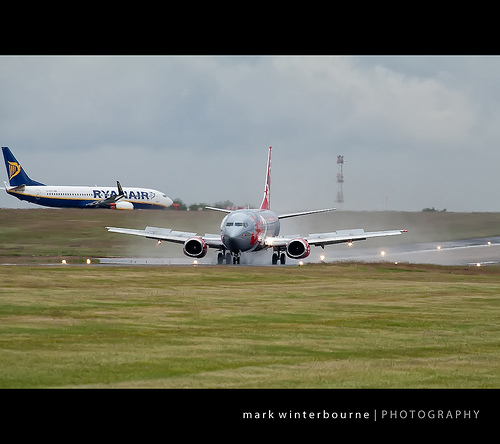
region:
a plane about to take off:
[112, 152, 424, 287]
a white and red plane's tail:
[258, 143, 286, 211]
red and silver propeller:
[283, 231, 315, 265]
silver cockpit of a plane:
[218, 212, 258, 257]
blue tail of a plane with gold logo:
[1, 143, 38, 189]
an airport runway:
[414, 231, 499, 268]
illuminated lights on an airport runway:
[316, 239, 495, 256]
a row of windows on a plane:
[47, 187, 94, 197]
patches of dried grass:
[133, 270, 385, 315]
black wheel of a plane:
[214, 246, 292, 275]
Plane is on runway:
[105, 214, 412, 271]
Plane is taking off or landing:
[1, 145, 186, 220]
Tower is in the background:
[323, 147, 354, 214]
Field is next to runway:
[8, 261, 496, 381]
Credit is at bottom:
[5, 392, 499, 428]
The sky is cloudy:
[1, 55, 497, 152]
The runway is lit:
[51, 214, 493, 268]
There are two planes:
[0, 142, 421, 267]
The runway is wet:
[78, 225, 478, 266]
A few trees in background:
[171, 197, 243, 214]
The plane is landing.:
[56, 148, 446, 305]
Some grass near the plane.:
[45, 280, 476, 370]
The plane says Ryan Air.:
[5, 142, 226, 232]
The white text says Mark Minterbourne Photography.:
[230, 397, 490, 425]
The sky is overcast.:
[33, 65, 488, 145]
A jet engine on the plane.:
[281, 235, 316, 261]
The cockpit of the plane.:
[213, 203, 253, 253]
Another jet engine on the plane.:
[180, 233, 205, 260]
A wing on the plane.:
[270, 220, 415, 247]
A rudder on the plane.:
[235, 135, 300, 218]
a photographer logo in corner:
[227, 392, 484, 427]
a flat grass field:
[4, 247, 487, 377]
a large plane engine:
[281, 235, 320, 268]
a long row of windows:
[38, 189, 105, 199]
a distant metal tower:
[326, 150, 359, 216]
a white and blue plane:
[0, 150, 187, 218]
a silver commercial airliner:
[111, 142, 414, 275]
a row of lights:
[323, 238, 492, 265]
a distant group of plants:
[155, 192, 235, 219]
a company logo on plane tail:
[4, 154, 26, 182]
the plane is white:
[167, 166, 356, 433]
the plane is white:
[125, 174, 316, 339]